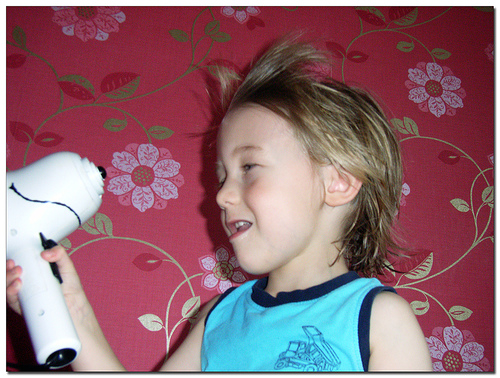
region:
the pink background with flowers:
[9, 11, 497, 376]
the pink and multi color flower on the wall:
[100, 140, 188, 215]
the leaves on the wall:
[9, 32, 208, 131]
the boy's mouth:
[222, 215, 253, 242]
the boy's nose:
[216, 174, 243, 209]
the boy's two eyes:
[214, 160, 264, 192]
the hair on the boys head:
[208, 35, 420, 276]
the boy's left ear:
[325, 158, 362, 205]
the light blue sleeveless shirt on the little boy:
[201, 275, 390, 374]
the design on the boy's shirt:
[275, 323, 340, 370]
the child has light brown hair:
[211, 57, 401, 280]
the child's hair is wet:
[213, 45, 415, 292]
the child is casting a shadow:
[199, 84, 264, 285]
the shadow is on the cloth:
[195, 85, 255, 285]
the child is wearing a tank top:
[200, 269, 385, 374]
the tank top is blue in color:
[200, 275, 380, 374]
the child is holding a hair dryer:
[6, 151, 128, 375]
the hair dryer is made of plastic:
[7, 152, 104, 375]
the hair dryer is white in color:
[10, 153, 102, 372]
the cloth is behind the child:
[6, 8, 488, 372]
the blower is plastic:
[13, 155, 118, 377]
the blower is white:
[8, 153, 98, 353]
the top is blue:
[216, 281, 361, 376]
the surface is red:
[86, 27, 208, 277]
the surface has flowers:
[93, 50, 213, 312]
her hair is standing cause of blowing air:
[198, 54, 414, 191]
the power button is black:
[39, 240, 69, 279]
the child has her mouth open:
[201, 116, 428, 376]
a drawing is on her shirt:
[273, 313, 324, 375]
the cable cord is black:
[0, 345, 81, 376]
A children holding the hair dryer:
[16, 12, 495, 362]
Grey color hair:
[196, 67, 418, 260]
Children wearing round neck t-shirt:
[212, 278, 412, 376]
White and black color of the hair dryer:
[13, 148, 112, 359]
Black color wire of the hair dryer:
[11, 357, 70, 372]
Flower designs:
[18, 11, 467, 320]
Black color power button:
[40, 232, 76, 283]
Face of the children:
[206, 106, 358, 303]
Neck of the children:
[278, 251, 366, 291]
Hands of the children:
[83, 329, 421, 371]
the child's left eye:
[238, 156, 264, 176]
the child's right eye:
[216, 174, 228, 188]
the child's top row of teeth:
[225, 219, 255, 231]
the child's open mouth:
[221, 215, 260, 242]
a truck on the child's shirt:
[266, 315, 346, 377]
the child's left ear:
[312, 150, 369, 210]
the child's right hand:
[0, 239, 111, 316]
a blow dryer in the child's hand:
[0, 150, 110, 370]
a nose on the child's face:
[213, 155, 240, 212]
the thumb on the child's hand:
[38, 240, 85, 287]